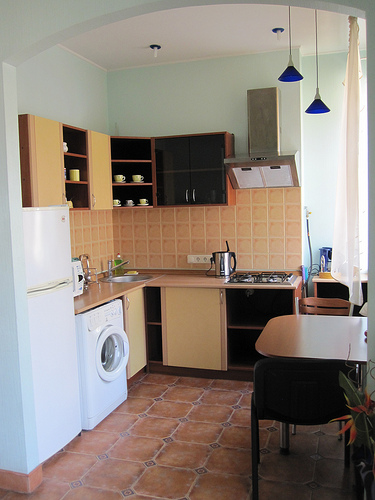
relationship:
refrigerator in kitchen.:
[20, 205, 82, 464] [0, 0, 373, 500]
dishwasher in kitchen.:
[75, 298, 131, 432] [0, 0, 373, 500]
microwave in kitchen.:
[69, 258, 87, 298] [0, 0, 373, 500]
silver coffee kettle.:
[208, 240, 240, 277] [205, 240, 237, 277]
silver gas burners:
[230, 272, 293, 284] [226, 270, 298, 286]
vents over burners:
[223, 86, 304, 191] [226, 270, 298, 286]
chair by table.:
[248, 356, 367, 496] [254, 313, 369, 364]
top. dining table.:
[254, 313, 368, 366] [254, 313, 369, 364]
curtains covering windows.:
[328, 15, 365, 307] [331, 14, 365, 306]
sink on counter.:
[99, 261, 155, 285] [73, 266, 301, 315]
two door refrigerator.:
[19, 203, 83, 462] [20, 205, 82, 464]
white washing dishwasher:
[74, 296, 132, 433] [75, 298, 131, 430]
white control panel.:
[72, 262, 86, 296] [73, 261, 85, 297]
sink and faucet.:
[99, 261, 155, 285] [106, 259, 131, 278]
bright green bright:
[112, 254, 126, 270] [114, 252, 124, 276]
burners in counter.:
[226, 270, 296, 284] [73, 266, 301, 315]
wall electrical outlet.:
[17, 42, 375, 298] [188, 255, 224, 263]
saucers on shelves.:
[111, 173, 152, 206] [60, 123, 156, 211]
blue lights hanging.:
[277, 3, 330, 115] [277, 5, 331, 116]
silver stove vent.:
[222, 87, 301, 191] [223, 86, 304, 191]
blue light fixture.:
[277, 3, 330, 115] [278, 6, 332, 115]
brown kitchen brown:
[110, 159, 150, 163] [110, 159, 150, 163]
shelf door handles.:
[90, 190, 99, 209] [89, 191, 98, 209]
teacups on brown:
[114, 172, 148, 185] [110, 159, 150, 163]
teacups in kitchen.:
[112, 197, 150, 207] [0, 0, 373, 500]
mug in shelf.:
[69, 169, 81, 181] [64, 179, 87, 185]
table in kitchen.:
[254, 313, 369, 364] [0, 0, 373, 500]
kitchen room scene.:
[0, 0, 373, 500] [0, 0, 374, 498]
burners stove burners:
[226, 270, 298, 286] [226, 270, 298, 286]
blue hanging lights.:
[277, 3, 330, 115] [278, 6, 332, 115]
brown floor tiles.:
[1, 368, 374, 499] [2, 373, 374, 500]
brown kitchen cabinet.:
[17, 114, 304, 381] [18, 113, 303, 380]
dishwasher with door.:
[75, 298, 131, 430] [95, 324, 130, 383]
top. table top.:
[254, 313, 368, 366] [254, 313, 368, 366]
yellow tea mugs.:
[112, 173, 148, 185] [113, 172, 147, 184]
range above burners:
[223, 86, 304, 191] [226, 270, 298, 286]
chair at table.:
[248, 356, 367, 496] [254, 313, 369, 364]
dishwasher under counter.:
[75, 298, 131, 430] [73, 266, 301, 315]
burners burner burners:
[226, 270, 298, 286] [226, 270, 298, 286]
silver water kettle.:
[208, 240, 240, 277] [208, 241, 237, 279]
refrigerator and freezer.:
[20, 205, 82, 464] [23, 205, 74, 297]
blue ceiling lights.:
[277, 3, 330, 115] [278, 6, 332, 115]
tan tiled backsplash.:
[69, 185, 302, 273] [67, 185, 302, 271]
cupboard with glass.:
[153, 133, 228, 208] [153, 133, 230, 206]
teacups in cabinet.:
[114, 172, 148, 185] [18, 113, 303, 380]